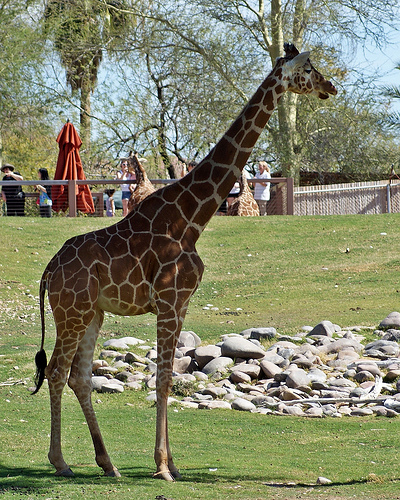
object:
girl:
[34, 168, 54, 217]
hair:
[37, 167, 50, 180]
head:
[267, 42, 338, 100]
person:
[119, 160, 132, 216]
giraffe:
[119, 151, 158, 213]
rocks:
[101, 338, 130, 351]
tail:
[29, 273, 46, 397]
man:
[0, 163, 26, 215]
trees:
[37, 0, 139, 171]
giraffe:
[227, 162, 260, 216]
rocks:
[194, 344, 221, 365]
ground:
[0, 211, 400, 500]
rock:
[221, 337, 266, 359]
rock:
[260, 360, 282, 378]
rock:
[286, 369, 311, 389]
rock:
[231, 398, 255, 410]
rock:
[203, 385, 227, 397]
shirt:
[254, 170, 271, 201]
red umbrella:
[49, 118, 96, 214]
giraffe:
[31, 42, 337, 483]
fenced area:
[1, 175, 399, 497]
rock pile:
[91, 309, 400, 418]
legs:
[43, 313, 83, 479]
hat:
[0, 163, 15, 172]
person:
[251, 161, 271, 215]